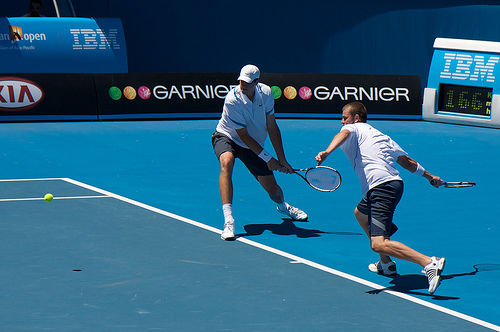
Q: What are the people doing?
A: Playing.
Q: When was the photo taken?
A: Daytime.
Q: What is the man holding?
A: Tennis rack.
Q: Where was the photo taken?
A: Tennis court.